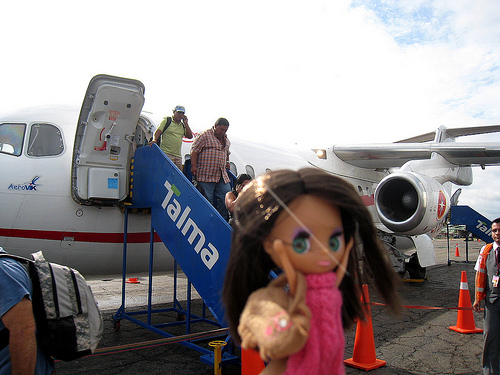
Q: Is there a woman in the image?
A: No, there are no women.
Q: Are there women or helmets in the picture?
A: No, there are no women or helmets.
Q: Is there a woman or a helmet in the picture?
A: No, there are no women or helmets.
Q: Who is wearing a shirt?
A: The man is wearing a shirt.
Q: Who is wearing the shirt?
A: The man is wearing a shirt.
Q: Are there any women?
A: No, there are no women.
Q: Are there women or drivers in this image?
A: No, there are no women or drivers.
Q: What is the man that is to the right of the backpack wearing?
A: The man is wearing a shirt.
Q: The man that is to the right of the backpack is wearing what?
A: The man is wearing a shirt.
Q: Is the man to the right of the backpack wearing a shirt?
A: Yes, the man is wearing a shirt.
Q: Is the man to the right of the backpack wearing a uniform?
A: No, the man is wearing a shirt.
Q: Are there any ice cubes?
A: No, there are no ice cubes.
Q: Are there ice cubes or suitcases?
A: No, there are no ice cubes or suitcases.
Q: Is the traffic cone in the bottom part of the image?
A: Yes, the traffic cone is in the bottom of the image.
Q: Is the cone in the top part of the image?
A: No, the cone is in the bottom of the image.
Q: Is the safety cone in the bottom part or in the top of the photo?
A: The safety cone is in the bottom of the image.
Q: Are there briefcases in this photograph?
A: No, there are no briefcases.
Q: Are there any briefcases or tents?
A: No, there are no briefcases or tents.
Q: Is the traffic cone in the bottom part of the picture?
A: Yes, the traffic cone is in the bottom of the image.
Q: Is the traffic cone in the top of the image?
A: No, the traffic cone is in the bottom of the image.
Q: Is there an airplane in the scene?
A: Yes, there is an airplane.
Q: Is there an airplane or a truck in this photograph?
A: Yes, there is an airplane.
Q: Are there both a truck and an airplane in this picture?
A: No, there is an airplane but no trucks.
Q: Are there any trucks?
A: No, there are no trucks.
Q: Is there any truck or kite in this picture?
A: No, there are no trucks or kites.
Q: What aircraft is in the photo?
A: The aircraft is an airplane.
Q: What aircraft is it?
A: The aircraft is an airplane.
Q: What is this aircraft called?
A: This is an airplane.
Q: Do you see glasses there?
A: No, there are no glasses.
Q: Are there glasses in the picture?
A: No, there are no glasses.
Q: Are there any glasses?
A: No, there are no glasses.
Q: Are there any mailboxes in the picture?
A: No, there are no mailboxes.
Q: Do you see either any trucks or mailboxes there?
A: No, there are no mailboxes or trucks.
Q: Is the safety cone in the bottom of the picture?
A: Yes, the safety cone is in the bottom of the image.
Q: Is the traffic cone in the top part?
A: No, the traffic cone is in the bottom of the image.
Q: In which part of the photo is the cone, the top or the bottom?
A: The cone is in the bottom of the image.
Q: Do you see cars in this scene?
A: No, there are no cars.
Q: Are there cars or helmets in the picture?
A: No, there are no cars or helmets.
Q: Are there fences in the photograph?
A: No, there are no fences.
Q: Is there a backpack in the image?
A: Yes, there is a backpack.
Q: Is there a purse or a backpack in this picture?
A: Yes, there is a backpack.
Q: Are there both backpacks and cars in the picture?
A: No, there is a backpack but no cars.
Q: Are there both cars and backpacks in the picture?
A: No, there is a backpack but no cars.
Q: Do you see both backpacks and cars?
A: No, there is a backpack but no cars.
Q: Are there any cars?
A: No, there are no cars.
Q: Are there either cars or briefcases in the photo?
A: No, there are no cars or briefcases.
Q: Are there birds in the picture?
A: No, there are no birds.